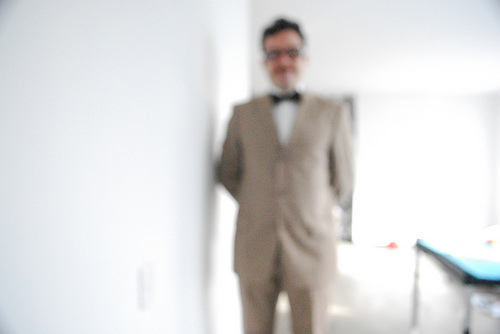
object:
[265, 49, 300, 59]
glasses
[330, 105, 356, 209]
arm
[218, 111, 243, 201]
arm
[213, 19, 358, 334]
man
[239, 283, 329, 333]
pants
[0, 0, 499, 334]
scene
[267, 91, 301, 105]
bow tie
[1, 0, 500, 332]
wall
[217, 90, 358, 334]
suit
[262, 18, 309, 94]
head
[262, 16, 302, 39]
hair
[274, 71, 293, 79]
mouth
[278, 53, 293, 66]
nose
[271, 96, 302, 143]
shirt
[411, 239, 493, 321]
table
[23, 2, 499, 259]
background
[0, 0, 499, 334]
section